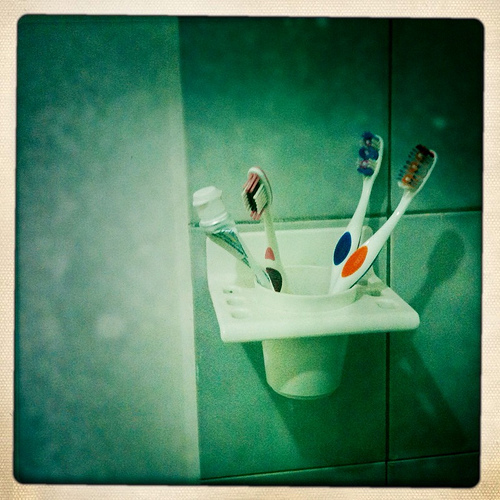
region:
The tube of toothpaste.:
[197, 187, 269, 288]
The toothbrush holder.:
[207, 236, 419, 347]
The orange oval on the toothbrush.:
[338, 246, 365, 277]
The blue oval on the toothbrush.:
[331, 235, 350, 263]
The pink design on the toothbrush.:
[261, 244, 273, 260]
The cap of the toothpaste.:
[190, 183, 227, 217]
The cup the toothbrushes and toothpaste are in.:
[250, 268, 350, 395]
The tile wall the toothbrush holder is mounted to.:
[187, 24, 479, 486]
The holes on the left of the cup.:
[223, 282, 250, 332]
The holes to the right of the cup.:
[360, 269, 395, 316]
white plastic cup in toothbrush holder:
[258, 270, 359, 397]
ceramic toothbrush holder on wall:
[205, 221, 422, 340]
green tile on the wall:
[182, 21, 478, 496]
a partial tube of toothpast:
[195, 187, 267, 289]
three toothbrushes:
[242, 130, 437, 291]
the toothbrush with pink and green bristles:
[241, 166, 286, 290]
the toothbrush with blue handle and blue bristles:
[334, 128, 384, 282]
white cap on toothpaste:
[194, 188, 224, 223]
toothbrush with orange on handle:
[335, 142, 437, 293]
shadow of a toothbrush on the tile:
[413, 231, 465, 327]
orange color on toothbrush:
[346, 255, 361, 266]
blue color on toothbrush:
[335, 240, 345, 250]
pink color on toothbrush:
[262, 246, 272, 256]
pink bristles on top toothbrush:
[245, 176, 256, 187]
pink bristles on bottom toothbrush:
[251, 213, 260, 220]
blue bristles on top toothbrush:
[364, 132, 374, 140]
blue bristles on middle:
[359, 147, 371, 155]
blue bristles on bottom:
[356, 165, 371, 175]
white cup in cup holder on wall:
[274, 367, 348, 396]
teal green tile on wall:
[212, 381, 244, 429]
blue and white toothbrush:
[327, 128, 384, 292]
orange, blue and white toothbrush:
[330, 141, 436, 287]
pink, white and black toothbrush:
[240, 165, 286, 295]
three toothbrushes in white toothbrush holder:
[235, 125, 440, 290]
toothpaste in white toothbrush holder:
[190, 185, 270, 295]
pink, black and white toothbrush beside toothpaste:
[236, 161, 281, 291]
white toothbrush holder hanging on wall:
[196, 220, 416, 396]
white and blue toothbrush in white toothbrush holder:
[325, 130, 380, 295]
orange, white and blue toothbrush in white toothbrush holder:
[320, 141, 440, 294]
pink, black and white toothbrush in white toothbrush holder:
[240, 166, 289, 297]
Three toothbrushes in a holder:
[242, 132, 438, 293]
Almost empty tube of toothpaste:
[185, 181, 275, 287]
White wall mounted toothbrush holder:
[200, 222, 420, 403]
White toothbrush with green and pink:
[240, 166, 292, 291]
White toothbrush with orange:
[327, 140, 438, 292]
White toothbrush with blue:
[325, 128, 386, 290]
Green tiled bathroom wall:
[170, 22, 480, 488]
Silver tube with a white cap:
[183, 181, 275, 293]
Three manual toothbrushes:
[237, 128, 437, 289]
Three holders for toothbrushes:
[219, 282, 252, 324]